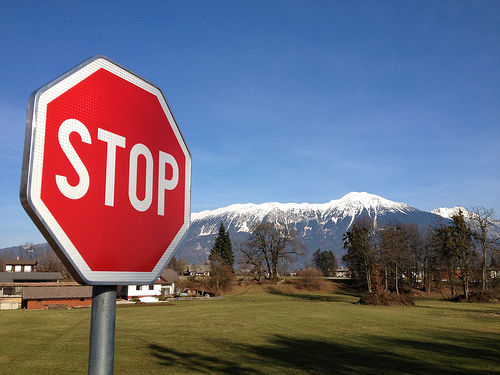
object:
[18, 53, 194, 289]
sign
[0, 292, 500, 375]
foreground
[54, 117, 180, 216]
stop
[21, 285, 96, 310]
buildings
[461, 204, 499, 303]
trees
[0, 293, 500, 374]
lawn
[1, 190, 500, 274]
mountain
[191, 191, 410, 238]
snow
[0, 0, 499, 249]
sky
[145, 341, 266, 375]
shadows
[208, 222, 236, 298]
tree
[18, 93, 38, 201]
border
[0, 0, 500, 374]
photo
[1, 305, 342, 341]
sun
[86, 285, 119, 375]
pole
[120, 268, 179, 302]
house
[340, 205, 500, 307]
grove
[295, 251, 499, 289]
area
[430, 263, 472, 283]
buildings